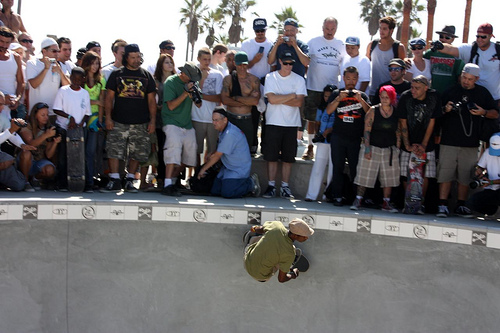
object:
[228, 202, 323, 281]
skater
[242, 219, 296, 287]
shirt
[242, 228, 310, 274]
skateboard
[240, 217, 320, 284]
man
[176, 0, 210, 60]
trees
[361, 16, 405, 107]
people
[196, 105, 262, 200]
man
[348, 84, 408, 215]
girl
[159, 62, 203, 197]
man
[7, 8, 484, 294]
picture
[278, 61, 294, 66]
sunglasses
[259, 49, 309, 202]
man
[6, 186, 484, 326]
skatebowl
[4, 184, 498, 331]
skate bowl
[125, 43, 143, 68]
head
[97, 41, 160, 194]
person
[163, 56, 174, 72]
head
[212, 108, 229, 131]
head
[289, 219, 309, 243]
head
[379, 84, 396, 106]
head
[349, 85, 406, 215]
person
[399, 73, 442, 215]
person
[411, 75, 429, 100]
head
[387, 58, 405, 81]
head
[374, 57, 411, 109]
person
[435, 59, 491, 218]
person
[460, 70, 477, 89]
head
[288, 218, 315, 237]
hat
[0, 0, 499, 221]
audience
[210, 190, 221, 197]
knees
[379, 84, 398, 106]
hair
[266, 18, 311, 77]
man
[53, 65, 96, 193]
man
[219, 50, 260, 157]
man